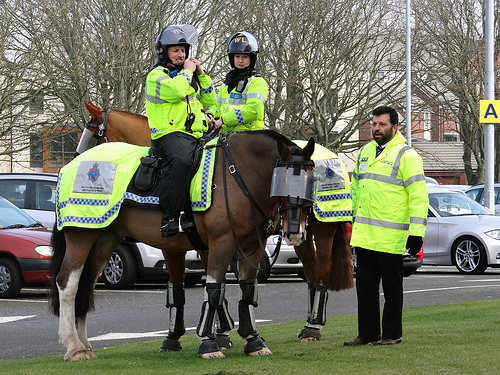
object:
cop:
[142, 22, 217, 239]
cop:
[204, 30, 271, 134]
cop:
[340, 105, 430, 347]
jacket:
[205, 68, 270, 135]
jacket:
[144, 64, 220, 141]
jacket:
[342, 128, 429, 255]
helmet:
[155, 24, 197, 47]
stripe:
[154, 76, 169, 100]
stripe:
[234, 108, 247, 125]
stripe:
[355, 172, 403, 187]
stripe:
[352, 216, 410, 231]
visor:
[159, 22, 198, 46]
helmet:
[223, 31, 261, 55]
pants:
[147, 133, 203, 216]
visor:
[72, 126, 106, 154]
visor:
[268, 167, 320, 203]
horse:
[43, 129, 318, 360]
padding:
[195, 281, 223, 338]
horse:
[73, 100, 355, 353]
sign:
[475, 99, 499, 124]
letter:
[482, 103, 499, 119]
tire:
[447, 234, 487, 274]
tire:
[99, 246, 138, 290]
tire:
[0, 258, 21, 298]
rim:
[453, 238, 482, 274]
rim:
[101, 254, 123, 285]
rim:
[0, 267, 10, 291]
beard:
[370, 128, 395, 146]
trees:
[0, 0, 493, 184]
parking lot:
[0, 241, 499, 374]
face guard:
[268, 167, 314, 200]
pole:
[482, 1, 495, 214]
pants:
[351, 246, 404, 339]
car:
[419, 187, 499, 276]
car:
[0, 194, 56, 300]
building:
[404, 141, 489, 186]